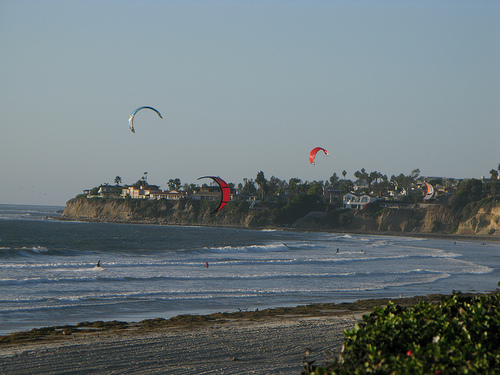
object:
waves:
[233, 237, 492, 286]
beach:
[13, 244, 498, 374]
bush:
[328, 285, 495, 367]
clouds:
[401, 47, 469, 92]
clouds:
[313, 78, 423, 148]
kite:
[200, 177, 231, 217]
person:
[89, 252, 109, 274]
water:
[0, 239, 494, 325]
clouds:
[398, 95, 428, 129]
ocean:
[0, 200, 496, 333]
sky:
[245, 32, 367, 94]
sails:
[109, 90, 349, 232]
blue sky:
[0, 2, 499, 206]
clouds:
[381, 70, 437, 124]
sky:
[39, 45, 494, 149]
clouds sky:
[299, 62, 410, 126]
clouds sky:
[55, 25, 221, 97]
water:
[0, 217, 498, 334]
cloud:
[252, 77, 301, 131]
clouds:
[363, 58, 447, 118]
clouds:
[390, 13, 462, 84]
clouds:
[338, 54, 423, 109]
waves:
[243, 247, 325, 306]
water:
[12, 218, 459, 301]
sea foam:
[201, 240, 291, 250]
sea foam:
[3, 257, 119, 276]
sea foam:
[259, 227, 279, 236]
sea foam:
[4, 272, 459, 304]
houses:
[85, 174, 488, 209]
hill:
[62, 172, 498, 236]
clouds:
[0, 0, 495, 170]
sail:
[126, 105, 163, 131]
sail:
[308, 146, 328, 164]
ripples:
[21, 210, 476, 332]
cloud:
[14, 26, 45, 62]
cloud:
[362, 102, 459, 146]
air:
[22, 20, 459, 173]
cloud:
[358, 111, 457, 161]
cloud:
[357, 119, 475, 170]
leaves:
[310, 294, 499, 374]